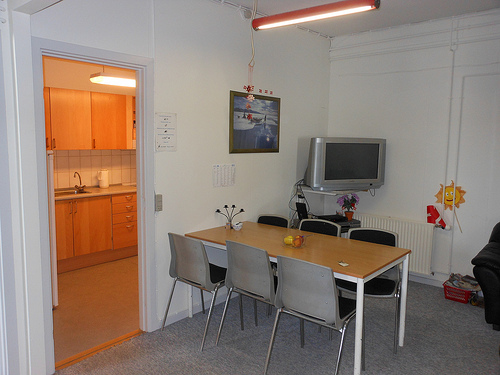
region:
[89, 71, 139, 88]
A light in the kitchen.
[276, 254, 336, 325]
The back of a grey chair.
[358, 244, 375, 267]
Part of the table.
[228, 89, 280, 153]
A painting on the wall.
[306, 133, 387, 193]
A tv in the corner.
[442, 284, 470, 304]
A red basket on the floor.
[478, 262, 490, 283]
Part of a couch.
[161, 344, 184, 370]
Part of the grey floor.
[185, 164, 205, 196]
Part of the wall.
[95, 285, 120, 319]
Part of the kitchen floor.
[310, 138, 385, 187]
an old style tv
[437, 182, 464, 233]
sun on the wall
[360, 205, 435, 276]
the radiator is white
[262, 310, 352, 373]
chair legs are metal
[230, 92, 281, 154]
picture on the wall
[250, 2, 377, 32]
light on the ceiling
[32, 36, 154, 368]
doorway to the kitchen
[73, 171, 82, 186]
faucet on the counter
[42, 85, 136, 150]
the cabinets are wood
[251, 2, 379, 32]
Light hanging in the room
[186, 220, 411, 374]
Table in the room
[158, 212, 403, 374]
Chairs in the room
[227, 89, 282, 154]
Picture hanging on the wall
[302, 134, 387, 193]
TV in the room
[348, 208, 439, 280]
Heater in the room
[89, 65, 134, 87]
Light in the kitchen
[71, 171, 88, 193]
Facet on the counter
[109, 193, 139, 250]
Drawers on the cabinets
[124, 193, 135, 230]
Handles on the drawers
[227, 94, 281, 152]
framed picture on the wall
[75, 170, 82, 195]
faucet on the kitchen skink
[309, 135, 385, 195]
a gray television on stand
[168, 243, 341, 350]
three chairs underneath table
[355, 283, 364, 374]
a leg on the table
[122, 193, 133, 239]
handles on the kitchen cabinet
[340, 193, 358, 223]
a flower in pot underneath television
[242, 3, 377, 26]
a red light in ceiling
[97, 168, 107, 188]
white pitcher on kitchen countertop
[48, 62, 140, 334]
this is a kitchen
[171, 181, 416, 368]
this is a dining table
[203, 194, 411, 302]
dining table is brown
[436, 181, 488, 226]
yellow sun on wall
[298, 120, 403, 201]
this is a television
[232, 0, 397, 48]
flourescant light above table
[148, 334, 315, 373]
grey carpet on the floor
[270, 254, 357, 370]
silver back of chair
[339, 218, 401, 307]
black seat and back rest of chair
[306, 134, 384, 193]
an old style television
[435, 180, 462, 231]
cutout of the sun on the wall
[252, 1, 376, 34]
florescent overhead light on the ceiling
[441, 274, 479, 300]
a small red basket on the ground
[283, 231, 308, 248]
fruit display on the middle of the table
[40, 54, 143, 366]
inside view of the kitchen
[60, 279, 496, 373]
gray carpeted floor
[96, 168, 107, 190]
A white coffee carafe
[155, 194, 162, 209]
A grey light switch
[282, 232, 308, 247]
A bowl of fruit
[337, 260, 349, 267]
A set of keys on a white keychain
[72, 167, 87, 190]
A stainless steel kitchen faucet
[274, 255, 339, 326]
A backrest of a grey chair